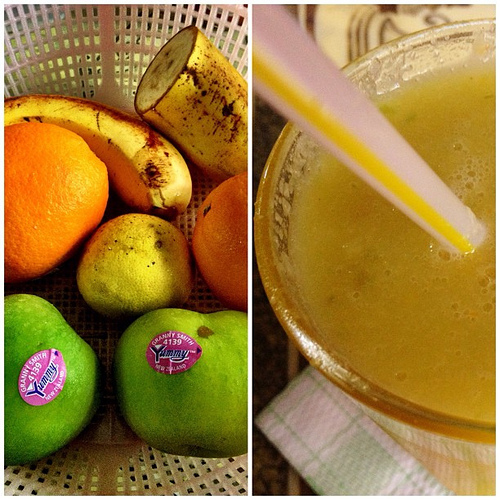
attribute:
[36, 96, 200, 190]
banana — yellow, single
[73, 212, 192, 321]
yellow pear — withered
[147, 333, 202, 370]
sticker — pink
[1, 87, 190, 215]
banana — unpeeled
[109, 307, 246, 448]
apple — green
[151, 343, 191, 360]
logo — blue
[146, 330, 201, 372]
label — purple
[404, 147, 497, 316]
juice — orange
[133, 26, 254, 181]
banana — brown 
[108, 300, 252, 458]
apple — green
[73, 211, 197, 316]
pear — yellow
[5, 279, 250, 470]
apples — green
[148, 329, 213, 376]
label — small, purple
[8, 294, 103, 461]
apple — unpeeled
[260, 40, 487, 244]
white straw — yellow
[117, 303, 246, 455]
apple — green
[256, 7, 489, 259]
straw — yellow, white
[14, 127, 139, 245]
orange — unpeeled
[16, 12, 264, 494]
basket — plastic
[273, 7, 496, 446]
liquid — yellow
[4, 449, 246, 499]
basket — white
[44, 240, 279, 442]
apple — green